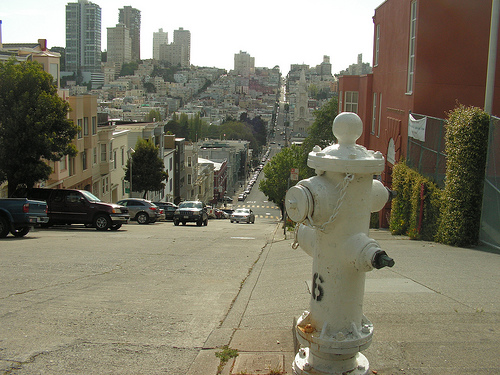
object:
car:
[172, 200, 209, 226]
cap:
[283, 185, 310, 224]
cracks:
[3, 237, 266, 374]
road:
[1, 87, 500, 375]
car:
[8, 186, 132, 233]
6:
[311, 272, 327, 302]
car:
[230, 208, 256, 224]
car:
[237, 193, 245, 200]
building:
[117, 4, 142, 62]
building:
[159, 41, 185, 67]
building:
[233, 50, 255, 70]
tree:
[0, 57, 76, 197]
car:
[113, 198, 166, 225]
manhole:
[230, 235, 255, 240]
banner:
[406, 113, 427, 143]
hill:
[1, 215, 498, 372]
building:
[63, 0, 103, 92]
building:
[291, 62, 312, 138]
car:
[157, 205, 177, 222]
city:
[1, 0, 498, 373]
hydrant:
[282, 112, 396, 375]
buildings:
[173, 73, 187, 83]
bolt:
[303, 322, 314, 333]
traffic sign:
[290, 167, 299, 182]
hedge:
[391, 103, 488, 252]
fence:
[403, 110, 500, 252]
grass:
[216, 345, 238, 362]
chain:
[305, 171, 354, 233]